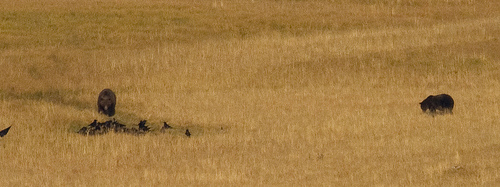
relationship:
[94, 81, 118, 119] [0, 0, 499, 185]
bear in field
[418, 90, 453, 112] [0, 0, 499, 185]
bear in field